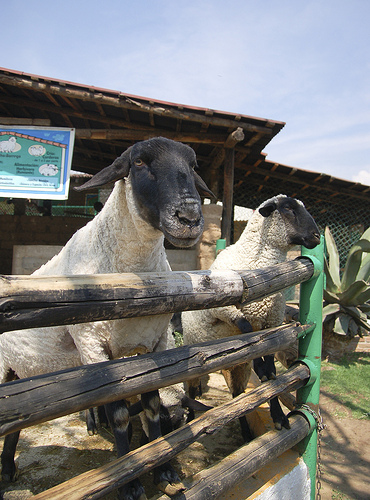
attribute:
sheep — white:
[181, 195, 322, 430]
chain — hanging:
[298, 398, 326, 498]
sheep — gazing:
[1, 134, 219, 442]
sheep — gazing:
[189, 193, 325, 435]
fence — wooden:
[320, 245, 365, 493]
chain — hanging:
[295, 394, 327, 499]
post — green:
[297, 232, 330, 498]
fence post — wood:
[0, 319, 316, 437]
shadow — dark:
[320, 350, 369, 498]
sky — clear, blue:
[272, 23, 368, 72]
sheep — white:
[3, 133, 202, 496]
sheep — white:
[39, 97, 309, 313]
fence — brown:
[60, 228, 361, 383]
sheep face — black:
[123, 130, 235, 245]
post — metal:
[294, 232, 325, 498]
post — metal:
[214, 236, 225, 253]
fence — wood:
[0, 234, 324, 497]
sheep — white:
[1, 134, 321, 483]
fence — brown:
[192, 280, 308, 421]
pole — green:
[301, 236, 327, 489]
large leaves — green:
[326, 223, 369, 335]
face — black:
[126, 130, 204, 233]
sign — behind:
[9, 115, 66, 219]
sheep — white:
[85, 130, 204, 318]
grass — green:
[273, 351, 369, 419]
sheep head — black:
[60, 131, 220, 259]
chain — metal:
[293, 383, 328, 497]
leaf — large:
[323, 225, 339, 286]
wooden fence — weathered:
[8, 328, 318, 495]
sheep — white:
[106, 148, 213, 228]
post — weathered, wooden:
[0, 266, 243, 333]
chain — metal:
[301, 401, 340, 494]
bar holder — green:
[82, 255, 352, 473]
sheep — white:
[0, 140, 228, 484]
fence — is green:
[6, 256, 355, 476]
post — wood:
[259, 256, 303, 276]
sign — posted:
[1, 122, 74, 202]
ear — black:
[76, 156, 132, 197]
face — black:
[119, 139, 214, 245]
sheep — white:
[7, 135, 220, 499]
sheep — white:
[179, 192, 318, 447]